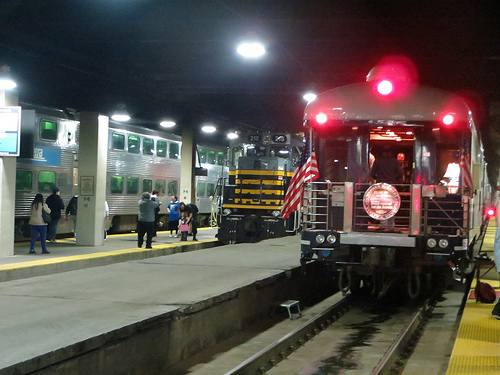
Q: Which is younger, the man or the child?
A: The child is younger than the man.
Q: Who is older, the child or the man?
A: The man is older than the child.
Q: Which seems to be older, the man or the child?
A: The man is older than the child.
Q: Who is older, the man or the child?
A: The man is older than the child.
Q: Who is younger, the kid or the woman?
A: The kid is younger than the woman.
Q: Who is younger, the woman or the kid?
A: The kid is younger than the woman.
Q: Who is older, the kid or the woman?
A: The woman is older than the kid.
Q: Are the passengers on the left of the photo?
A: Yes, the passengers are on the left of the image.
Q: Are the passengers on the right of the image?
A: No, the passengers are on the left of the image.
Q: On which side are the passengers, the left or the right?
A: The passengers are on the left of the image.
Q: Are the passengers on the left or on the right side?
A: The passengers are on the left of the image.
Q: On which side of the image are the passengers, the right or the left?
A: The passengers are on the left of the image.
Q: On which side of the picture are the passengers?
A: The passengers are on the left of the image.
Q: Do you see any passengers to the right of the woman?
A: Yes, there are passengers to the right of the woman.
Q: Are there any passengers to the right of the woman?
A: Yes, there are passengers to the right of the woman.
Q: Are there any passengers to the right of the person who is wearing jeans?
A: Yes, there are passengers to the right of the woman.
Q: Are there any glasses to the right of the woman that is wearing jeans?
A: No, there are passengers to the right of the woman.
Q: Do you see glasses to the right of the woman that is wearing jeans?
A: No, there are passengers to the right of the woman.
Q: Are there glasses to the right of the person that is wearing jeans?
A: No, there are passengers to the right of the woman.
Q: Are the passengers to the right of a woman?
A: Yes, the passengers are to the right of a woman.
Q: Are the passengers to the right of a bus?
A: No, the passengers are to the right of a woman.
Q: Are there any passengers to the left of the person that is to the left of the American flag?
A: Yes, there are passengers to the left of the person.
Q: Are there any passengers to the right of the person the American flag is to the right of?
A: No, the passengers are to the left of the person.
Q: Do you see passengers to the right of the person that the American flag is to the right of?
A: No, the passengers are to the left of the person.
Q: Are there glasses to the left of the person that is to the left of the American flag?
A: No, there are passengers to the left of the person.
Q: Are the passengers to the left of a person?
A: Yes, the passengers are to the left of a person.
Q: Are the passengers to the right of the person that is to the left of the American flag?
A: No, the passengers are to the left of the person.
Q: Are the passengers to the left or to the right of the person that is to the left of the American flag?
A: The passengers are to the left of the person.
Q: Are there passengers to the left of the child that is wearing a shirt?
A: Yes, there are passengers to the left of the kid.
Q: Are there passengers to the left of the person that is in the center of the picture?
A: Yes, there are passengers to the left of the kid.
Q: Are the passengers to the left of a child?
A: Yes, the passengers are to the left of a child.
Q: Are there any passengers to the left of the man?
A: Yes, there are passengers to the left of the man.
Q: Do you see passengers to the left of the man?
A: Yes, there are passengers to the left of the man.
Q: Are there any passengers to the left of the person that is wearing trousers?
A: Yes, there are passengers to the left of the man.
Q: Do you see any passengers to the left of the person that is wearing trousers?
A: Yes, there are passengers to the left of the man.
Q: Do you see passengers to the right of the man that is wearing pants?
A: No, the passengers are to the left of the man.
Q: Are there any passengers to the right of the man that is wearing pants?
A: No, the passengers are to the left of the man.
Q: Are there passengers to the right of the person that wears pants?
A: No, the passengers are to the left of the man.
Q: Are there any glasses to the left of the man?
A: No, there are passengers to the left of the man.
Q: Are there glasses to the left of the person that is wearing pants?
A: No, there are passengers to the left of the man.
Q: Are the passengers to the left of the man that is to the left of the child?
A: Yes, the passengers are to the left of the man.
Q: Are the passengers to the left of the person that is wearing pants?
A: Yes, the passengers are to the left of the man.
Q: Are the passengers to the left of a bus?
A: No, the passengers are to the left of the man.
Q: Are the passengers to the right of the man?
A: No, the passengers are to the left of the man.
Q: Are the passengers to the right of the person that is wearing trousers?
A: No, the passengers are to the left of the man.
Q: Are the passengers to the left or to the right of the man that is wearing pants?
A: The passengers are to the left of the man.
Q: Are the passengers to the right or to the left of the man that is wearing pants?
A: The passengers are to the left of the man.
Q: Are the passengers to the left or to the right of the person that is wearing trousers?
A: The passengers are to the left of the man.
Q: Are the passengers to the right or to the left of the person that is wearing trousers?
A: The passengers are to the left of the man.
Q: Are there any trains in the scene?
A: Yes, there is a train.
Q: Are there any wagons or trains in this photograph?
A: Yes, there is a train.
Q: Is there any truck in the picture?
A: No, there are no trucks.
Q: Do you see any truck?
A: No, there are no trucks.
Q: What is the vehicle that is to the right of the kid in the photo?
A: The vehicle is a train.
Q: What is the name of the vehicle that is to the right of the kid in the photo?
A: The vehicle is a train.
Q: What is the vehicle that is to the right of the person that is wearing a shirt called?
A: The vehicle is a train.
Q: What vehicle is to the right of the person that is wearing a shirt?
A: The vehicle is a train.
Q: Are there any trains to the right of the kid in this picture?
A: Yes, there is a train to the right of the kid.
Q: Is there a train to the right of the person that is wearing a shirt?
A: Yes, there is a train to the right of the kid.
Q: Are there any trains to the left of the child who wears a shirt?
A: No, the train is to the right of the kid.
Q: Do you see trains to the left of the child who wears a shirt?
A: No, the train is to the right of the kid.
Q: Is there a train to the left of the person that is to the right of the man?
A: No, the train is to the right of the kid.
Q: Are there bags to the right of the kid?
A: No, there is a train to the right of the kid.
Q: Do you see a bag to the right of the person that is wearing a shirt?
A: No, there is a train to the right of the kid.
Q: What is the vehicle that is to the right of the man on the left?
A: The vehicle is a train.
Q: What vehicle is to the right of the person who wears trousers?
A: The vehicle is a train.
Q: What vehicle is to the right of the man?
A: The vehicle is a train.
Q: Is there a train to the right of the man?
A: Yes, there is a train to the right of the man.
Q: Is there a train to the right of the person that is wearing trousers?
A: Yes, there is a train to the right of the man.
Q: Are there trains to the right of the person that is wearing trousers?
A: Yes, there is a train to the right of the man.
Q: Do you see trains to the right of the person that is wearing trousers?
A: Yes, there is a train to the right of the man.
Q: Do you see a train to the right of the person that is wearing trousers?
A: Yes, there is a train to the right of the man.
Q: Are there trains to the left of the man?
A: No, the train is to the right of the man.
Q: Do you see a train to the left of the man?
A: No, the train is to the right of the man.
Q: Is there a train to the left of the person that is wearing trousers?
A: No, the train is to the right of the man.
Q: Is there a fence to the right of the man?
A: No, there is a train to the right of the man.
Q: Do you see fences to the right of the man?
A: No, there is a train to the right of the man.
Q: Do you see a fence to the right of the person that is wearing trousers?
A: No, there is a train to the right of the man.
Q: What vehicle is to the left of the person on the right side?
A: The vehicle is a train.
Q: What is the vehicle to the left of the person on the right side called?
A: The vehicle is a train.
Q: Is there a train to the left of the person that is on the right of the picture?
A: Yes, there is a train to the left of the person.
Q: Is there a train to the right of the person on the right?
A: No, the train is to the left of the person.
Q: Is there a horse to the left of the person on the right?
A: No, there is a train to the left of the person.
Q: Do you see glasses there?
A: No, there are no glasses.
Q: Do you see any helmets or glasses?
A: No, there are no glasses or helmets.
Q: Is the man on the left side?
A: Yes, the man is on the left of the image.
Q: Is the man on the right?
A: No, the man is on the left of the image.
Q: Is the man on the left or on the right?
A: The man is on the left of the image.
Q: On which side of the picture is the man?
A: The man is on the left of the image.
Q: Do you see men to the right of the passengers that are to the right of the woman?
A: Yes, there is a man to the right of the passengers.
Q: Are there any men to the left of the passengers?
A: No, the man is to the right of the passengers.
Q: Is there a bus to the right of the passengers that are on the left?
A: No, there is a man to the right of the passengers.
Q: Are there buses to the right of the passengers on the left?
A: No, there is a man to the right of the passengers.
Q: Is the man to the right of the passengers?
A: Yes, the man is to the right of the passengers.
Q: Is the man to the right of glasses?
A: No, the man is to the right of the passengers.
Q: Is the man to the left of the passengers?
A: No, the man is to the right of the passengers.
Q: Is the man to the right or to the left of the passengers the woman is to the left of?
A: The man is to the right of the passengers.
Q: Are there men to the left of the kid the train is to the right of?
A: Yes, there is a man to the left of the child.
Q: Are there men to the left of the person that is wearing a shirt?
A: Yes, there is a man to the left of the child.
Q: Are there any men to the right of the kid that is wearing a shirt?
A: No, the man is to the left of the child.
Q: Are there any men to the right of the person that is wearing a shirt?
A: No, the man is to the left of the child.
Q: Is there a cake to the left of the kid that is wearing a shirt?
A: No, there is a man to the left of the child.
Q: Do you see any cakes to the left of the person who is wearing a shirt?
A: No, there is a man to the left of the child.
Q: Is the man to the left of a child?
A: Yes, the man is to the left of a child.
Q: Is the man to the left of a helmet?
A: No, the man is to the left of a child.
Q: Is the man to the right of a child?
A: No, the man is to the left of a child.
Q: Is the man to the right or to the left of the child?
A: The man is to the left of the child.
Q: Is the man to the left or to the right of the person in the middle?
A: The man is to the left of the child.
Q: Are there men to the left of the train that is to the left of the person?
A: Yes, there is a man to the left of the train.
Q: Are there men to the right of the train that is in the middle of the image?
A: No, the man is to the left of the train.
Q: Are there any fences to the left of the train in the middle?
A: No, there is a man to the left of the train.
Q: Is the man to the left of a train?
A: Yes, the man is to the left of a train.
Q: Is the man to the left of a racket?
A: No, the man is to the left of a train.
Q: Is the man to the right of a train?
A: No, the man is to the left of a train.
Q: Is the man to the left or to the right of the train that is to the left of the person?
A: The man is to the left of the train.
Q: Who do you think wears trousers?
A: The man wears trousers.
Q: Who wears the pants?
A: The man wears trousers.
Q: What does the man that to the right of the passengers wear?
A: The man wears pants.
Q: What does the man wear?
A: The man wears pants.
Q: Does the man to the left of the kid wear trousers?
A: Yes, the man wears trousers.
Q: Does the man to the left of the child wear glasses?
A: No, the man wears trousers.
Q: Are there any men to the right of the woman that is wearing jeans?
A: Yes, there is a man to the right of the woman.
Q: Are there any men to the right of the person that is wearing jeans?
A: Yes, there is a man to the right of the woman.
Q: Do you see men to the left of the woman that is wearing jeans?
A: No, the man is to the right of the woman.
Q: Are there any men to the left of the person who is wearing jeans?
A: No, the man is to the right of the woman.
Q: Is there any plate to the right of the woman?
A: No, there is a man to the right of the woman.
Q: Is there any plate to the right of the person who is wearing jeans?
A: No, there is a man to the right of the woman.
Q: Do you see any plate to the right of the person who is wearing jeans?
A: No, there is a man to the right of the woman.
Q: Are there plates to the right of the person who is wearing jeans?
A: No, there is a man to the right of the woman.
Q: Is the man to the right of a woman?
A: Yes, the man is to the right of a woman.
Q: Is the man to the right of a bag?
A: No, the man is to the right of a woman.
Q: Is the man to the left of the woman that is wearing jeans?
A: No, the man is to the right of the woman.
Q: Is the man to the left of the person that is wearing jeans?
A: No, the man is to the right of the woman.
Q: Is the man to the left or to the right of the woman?
A: The man is to the right of the woman.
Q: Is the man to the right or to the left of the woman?
A: The man is to the right of the woman.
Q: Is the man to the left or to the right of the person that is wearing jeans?
A: The man is to the right of the woman.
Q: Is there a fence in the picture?
A: No, there are no fences.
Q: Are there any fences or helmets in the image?
A: No, there are no fences or helmets.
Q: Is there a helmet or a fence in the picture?
A: No, there are no fences or helmets.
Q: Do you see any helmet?
A: No, there are no helmets.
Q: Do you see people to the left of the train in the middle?
A: Yes, there is a person to the left of the train.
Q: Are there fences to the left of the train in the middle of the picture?
A: No, there is a person to the left of the train.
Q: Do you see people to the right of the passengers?
A: Yes, there is a person to the right of the passengers.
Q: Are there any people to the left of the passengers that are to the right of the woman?
A: No, the person is to the right of the passengers.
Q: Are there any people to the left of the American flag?
A: Yes, there is a person to the left of the American flag.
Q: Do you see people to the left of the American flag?
A: Yes, there is a person to the left of the American flag.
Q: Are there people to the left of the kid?
A: Yes, there is a person to the left of the kid.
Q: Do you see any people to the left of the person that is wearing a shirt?
A: Yes, there is a person to the left of the kid.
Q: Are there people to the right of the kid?
A: No, the person is to the left of the kid.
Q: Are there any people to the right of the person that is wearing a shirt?
A: No, the person is to the left of the kid.